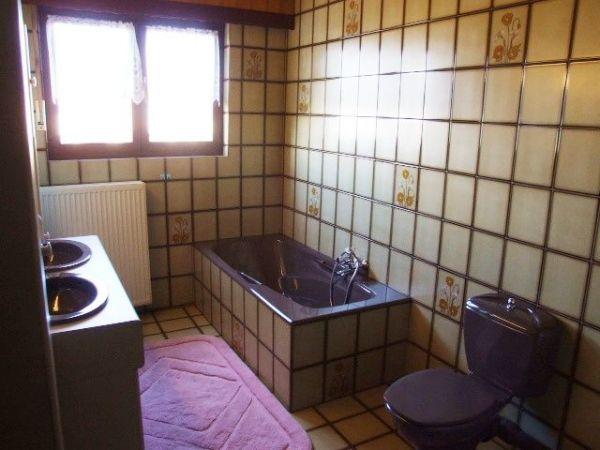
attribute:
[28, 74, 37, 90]
knob — white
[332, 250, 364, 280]
faucet — siver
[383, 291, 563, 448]
bowl — purple, toilet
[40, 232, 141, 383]
sink — double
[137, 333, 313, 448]
carpet — pink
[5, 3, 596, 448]
bathroom — tile finished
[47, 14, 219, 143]
window — bright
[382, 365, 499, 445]
bowl — closed, toilet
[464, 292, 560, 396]
cistern — purple, toilet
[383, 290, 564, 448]
system — bowl, cistern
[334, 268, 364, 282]
faucet — bathtub, water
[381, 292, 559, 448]
toilet — blue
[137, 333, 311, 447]
rug — purple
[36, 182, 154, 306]
radiator — heating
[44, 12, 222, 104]
curtains — white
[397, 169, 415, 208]
pattern — floral